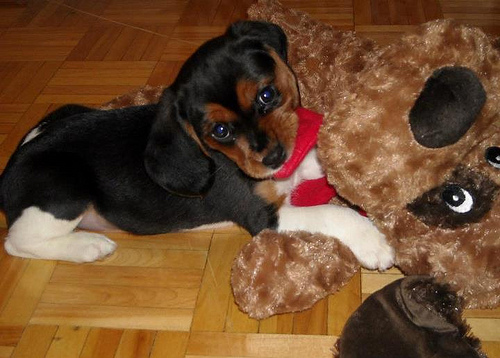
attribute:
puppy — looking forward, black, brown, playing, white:
[0, 19, 395, 271]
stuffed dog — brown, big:
[228, 1, 499, 358]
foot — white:
[4, 207, 118, 264]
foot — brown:
[98, 82, 170, 108]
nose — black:
[261, 148, 284, 165]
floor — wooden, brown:
[2, 1, 251, 166]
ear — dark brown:
[334, 276, 486, 356]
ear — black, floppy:
[143, 85, 218, 199]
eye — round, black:
[256, 84, 278, 105]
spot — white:
[21, 123, 46, 146]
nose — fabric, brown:
[410, 64, 485, 149]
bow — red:
[271, 98, 339, 207]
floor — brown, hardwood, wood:
[3, 227, 399, 357]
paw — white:
[286, 203, 397, 273]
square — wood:
[67, 23, 176, 61]